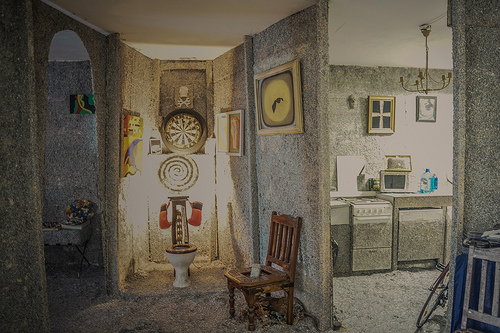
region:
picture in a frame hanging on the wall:
[364, 91, 396, 139]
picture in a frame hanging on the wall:
[252, 56, 306, 140]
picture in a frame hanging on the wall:
[227, 107, 247, 162]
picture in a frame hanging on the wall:
[212, 109, 232, 159]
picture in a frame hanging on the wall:
[412, 92, 441, 128]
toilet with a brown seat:
[153, 194, 212, 296]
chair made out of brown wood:
[216, 206, 308, 329]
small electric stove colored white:
[342, 191, 399, 280]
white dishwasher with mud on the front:
[397, 206, 445, 273]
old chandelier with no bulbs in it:
[392, 22, 454, 98]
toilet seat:
[170, 228, 207, 294]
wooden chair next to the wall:
[206, 206, 321, 331]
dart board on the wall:
[152, 95, 212, 156]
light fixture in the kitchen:
[398, 22, 470, 115]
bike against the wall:
[413, 228, 478, 330]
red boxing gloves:
[150, 188, 215, 244]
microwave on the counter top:
[369, 162, 421, 196]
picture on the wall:
[414, 94, 440, 125]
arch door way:
[24, 16, 137, 322]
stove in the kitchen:
[337, 188, 402, 281]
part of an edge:
[310, 177, 332, 215]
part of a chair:
[262, 270, 276, 290]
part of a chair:
[256, 272, 278, 298]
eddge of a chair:
[236, 270, 265, 302]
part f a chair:
[279, 258, 290, 283]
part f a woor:
[285, 259, 298, 287]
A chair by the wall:
[223, 209, 302, 327]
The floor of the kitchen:
[336, 263, 447, 332]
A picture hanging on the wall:
[366, 94, 396, 136]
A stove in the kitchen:
[341, 197, 394, 270]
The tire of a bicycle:
[419, 261, 451, 327]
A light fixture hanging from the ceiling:
[402, 23, 453, 95]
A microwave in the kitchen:
[380, 169, 415, 191]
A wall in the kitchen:
[329, 64, 452, 190]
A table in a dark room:
[43, 224, 95, 276]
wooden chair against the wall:
[220, 212, 301, 325]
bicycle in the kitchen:
[415, 262, 450, 332]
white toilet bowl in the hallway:
[166, 240, 196, 287]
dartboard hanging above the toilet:
[162, 110, 204, 152]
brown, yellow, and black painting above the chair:
[253, 67, 302, 139]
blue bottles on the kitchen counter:
[417, 169, 441, 194]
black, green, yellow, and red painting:
[68, 94, 93, 118]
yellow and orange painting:
[226, 113, 243, 160]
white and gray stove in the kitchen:
[349, 202, 395, 274]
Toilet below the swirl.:
[162, 241, 197, 287]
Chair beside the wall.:
[224, 208, 304, 331]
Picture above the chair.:
[253, 56, 303, 137]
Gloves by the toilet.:
[159, 197, 201, 229]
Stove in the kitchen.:
[351, 196, 394, 273]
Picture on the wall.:
[366, 91, 394, 136]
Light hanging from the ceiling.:
[399, 21, 452, 94]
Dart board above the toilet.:
[162, 111, 202, 149]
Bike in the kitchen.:
[415, 250, 451, 328]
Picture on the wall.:
[416, 92, 436, 120]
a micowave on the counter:
[377, 165, 413, 195]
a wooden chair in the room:
[217, 207, 314, 331]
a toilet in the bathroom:
[162, 189, 195, 290]